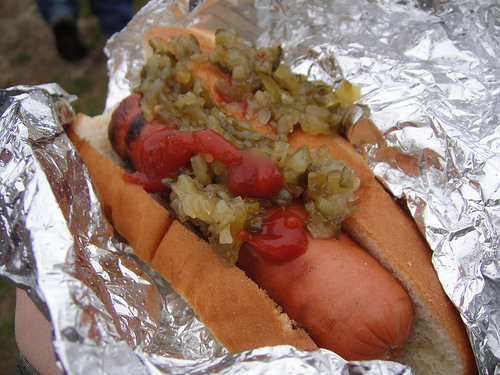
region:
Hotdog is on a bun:
[62, 22, 458, 368]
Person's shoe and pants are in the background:
[26, 5, 131, 60]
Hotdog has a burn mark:
[91, 100, 153, 150]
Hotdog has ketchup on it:
[91, 45, 408, 350]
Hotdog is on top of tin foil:
[30, 65, 490, 360]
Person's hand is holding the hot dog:
[10, 290, 57, 370]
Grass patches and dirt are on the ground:
[5, 11, 100, 103]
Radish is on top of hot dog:
[116, 21, 377, 256]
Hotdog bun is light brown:
[101, 31, 401, 373]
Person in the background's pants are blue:
[33, 3, 143, 54]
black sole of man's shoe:
[38, 5, 93, 68]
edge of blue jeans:
[36, 4, 85, 26]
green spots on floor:
[9, 39, 71, 77]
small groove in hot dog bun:
[130, 212, 195, 269]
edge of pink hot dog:
[357, 323, 422, 359]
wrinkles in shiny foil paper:
[396, 130, 498, 221]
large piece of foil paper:
[345, 10, 477, 113]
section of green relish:
[143, 64, 233, 127]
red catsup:
[131, 120, 289, 191]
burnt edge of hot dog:
[106, 90, 156, 145]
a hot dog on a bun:
[76, 110, 448, 354]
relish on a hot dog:
[291, 131, 368, 243]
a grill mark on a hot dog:
[253, 259, 353, 341]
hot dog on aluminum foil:
[13, 74, 493, 363]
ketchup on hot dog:
[238, 216, 307, 278]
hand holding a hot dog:
[11, 294, 58, 374]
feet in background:
[26, 3, 126, 63]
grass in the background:
[13, 17, 55, 87]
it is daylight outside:
[21, 21, 480, 365]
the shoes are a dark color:
[26, 10, 143, 62]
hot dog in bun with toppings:
[70, 25, 476, 371]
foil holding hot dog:
[0, 0, 495, 370]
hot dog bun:
[72, 21, 472, 371]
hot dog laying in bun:
[110, 91, 415, 361]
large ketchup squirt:
[120, 120, 285, 200]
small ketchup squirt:
[235, 212, 306, 258]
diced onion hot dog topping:
[135, 30, 360, 266]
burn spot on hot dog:
[120, 107, 145, 144]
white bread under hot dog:
[70, 25, 465, 371]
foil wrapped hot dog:
[2, 1, 497, 371]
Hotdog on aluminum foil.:
[31, 27, 482, 372]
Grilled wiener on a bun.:
[70, 25, 479, 374]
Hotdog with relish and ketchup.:
[68, 19, 474, 372]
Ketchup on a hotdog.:
[130, 123, 305, 265]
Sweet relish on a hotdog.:
[133, 29, 363, 132]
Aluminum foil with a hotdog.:
[319, 2, 497, 79]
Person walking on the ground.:
[25, 0, 140, 65]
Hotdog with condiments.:
[65, 25, 478, 373]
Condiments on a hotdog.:
[130, 27, 365, 262]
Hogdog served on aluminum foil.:
[70, 27, 471, 374]